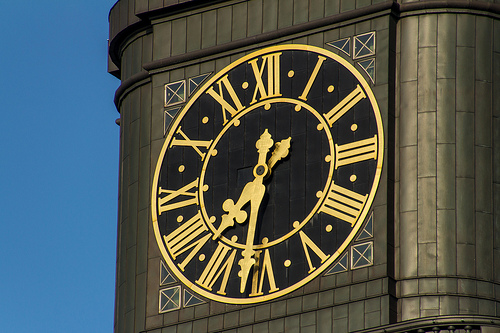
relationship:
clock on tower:
[148, 42, 385, 305] [108, 1, 499, 332]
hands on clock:
[213, 128, 291, 293] [148, 42, 385, 305]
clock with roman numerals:
[148, 42, 385, 305] [248, 52, 284, 105]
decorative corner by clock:
[157, 260, 208, 316] [148, 42, 385, 305]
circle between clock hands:
[230, 233, 239, 242] [213, 128, 291, 293]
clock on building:
[148, 42, 385, 305] [108, 1, 499, 332]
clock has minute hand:
[148, 42, 385, 305] [237, 128, 273, 294]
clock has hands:
[148, 42, 385, 305] [211, 128, 291, 293]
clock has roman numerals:
[148, 42, 385, 305] [248, 52, 284, 105]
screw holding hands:
[257, 166, 266, 175] [213, 128, 291, 293]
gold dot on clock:
[287, 69, 296, 79] [148, 42, 385, 305]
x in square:
[166, 83, 184, 102] [164, 80, 187, 107]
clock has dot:
[148, 42, 385, 305] [350, 122, 359, 133]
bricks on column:
[396, 13, 499, 320] [105, 32, 479, 297]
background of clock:
[168, 74, 406, 313] [148, 42, 385, 305]